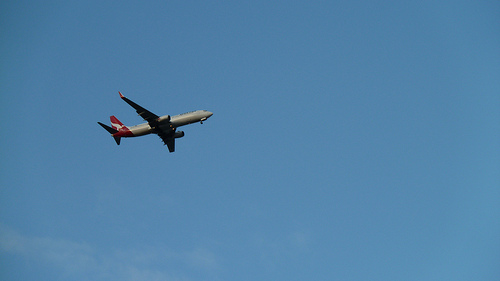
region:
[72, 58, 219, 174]
the plane is flying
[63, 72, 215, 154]
plane in the sky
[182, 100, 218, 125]
front of the plane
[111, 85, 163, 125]
wings of the plane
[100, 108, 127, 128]
tail of the plane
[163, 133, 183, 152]
wing of the plane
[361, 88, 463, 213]
the sky is clear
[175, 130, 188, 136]
engine of the plane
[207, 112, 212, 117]
nose of hte plane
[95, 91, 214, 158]
an airplane flying in the sky.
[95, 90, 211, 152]
an airplane flying in the sky.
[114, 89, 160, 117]
right wing on plane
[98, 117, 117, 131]
right tail on plane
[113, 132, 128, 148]
left tail on plane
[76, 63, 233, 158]
gray plane in sky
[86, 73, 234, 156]
plane is blue in sky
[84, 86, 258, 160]
gray plane in blue sky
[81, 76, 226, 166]
plane flying in sky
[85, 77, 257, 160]
plane in blue sky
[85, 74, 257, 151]
gray plane level in sky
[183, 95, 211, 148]
The plane is a deep gray color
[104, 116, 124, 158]
There is red on the tail of the plane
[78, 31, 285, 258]
The airplane was designed by an engineer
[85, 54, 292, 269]
This plane is a marvel of American engineering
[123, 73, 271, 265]
this is not a commercial airplane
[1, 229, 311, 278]
white tufts of clouds in blue sky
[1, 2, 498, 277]
clear blue sky with few wispy white clouds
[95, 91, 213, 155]
silver plane with red wings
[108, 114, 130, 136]
red tail wing on a silver plane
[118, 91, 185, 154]
dark underbelly of a silver plane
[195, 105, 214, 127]
nose and cockpit of a large silver plane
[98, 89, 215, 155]
silver plane flying in blue sky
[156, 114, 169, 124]
silver engine of a plane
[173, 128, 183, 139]
silver engine of a plane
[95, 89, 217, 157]
silver plane with red wings flying in blue sky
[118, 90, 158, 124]
A wing on a plane.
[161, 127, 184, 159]
A wing on a plane.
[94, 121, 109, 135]
A wing on a plane.